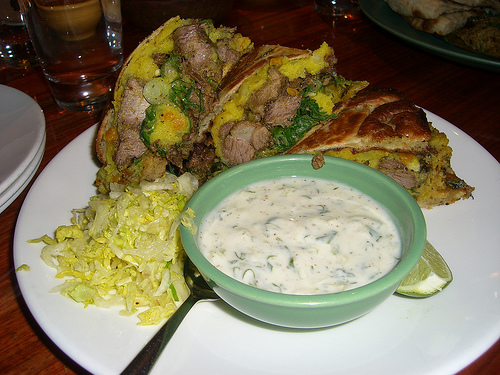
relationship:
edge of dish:
[263, 291, 353, 309] [177, 155, 427, 329]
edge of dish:
[400, 187, 427, 273] [177, 155, 427, 329]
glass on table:
[27, 6, 121, 116] [2, 20, 497, 372]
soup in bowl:
[198, 172, 400, 294] [176, 151, 428, 331]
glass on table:
[30, 0, 115, 111] [2, 20, 497, 372]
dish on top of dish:
[0, 81, 46, 218] [0, 81, 46, 218]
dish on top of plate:
[0, 81, 46, 218] [1, 146, 46, 212]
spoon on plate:
[102, 254, 236, 374] [13, 33, 494, 374]